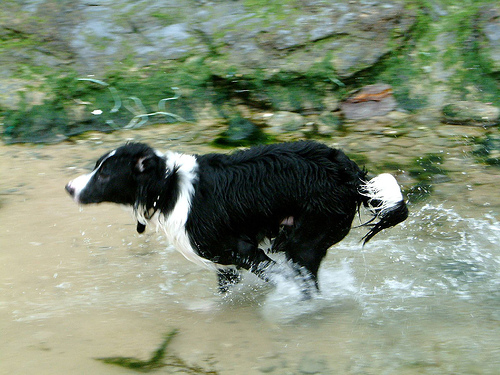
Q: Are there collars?
A: Yes, there is a collar.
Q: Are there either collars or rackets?
A: Yes, there is a collar.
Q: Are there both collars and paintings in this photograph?
A: No, there is a collar but no paintings.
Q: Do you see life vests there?
A: No, there are no life vests.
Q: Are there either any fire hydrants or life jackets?
A: No, there are no life jackets or fire hydrants.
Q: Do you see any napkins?
A: No, there are no napkins.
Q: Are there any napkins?
A: No, there are no napkins.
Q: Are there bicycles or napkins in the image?
A: No, there are no napkins or bicycles.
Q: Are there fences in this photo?
A: No, there are no fences.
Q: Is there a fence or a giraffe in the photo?
A: No, there are no fences or giraffes.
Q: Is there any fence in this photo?
A: No, there are no fences.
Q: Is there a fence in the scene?
A: No, there are no fences.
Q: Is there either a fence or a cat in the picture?
A: No, there are no fences or cats.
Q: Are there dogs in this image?
A: Yes, there is a dog.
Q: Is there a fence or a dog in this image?
A: Yes, there is a dog.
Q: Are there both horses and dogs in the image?
A: No, there is a dog but no horses.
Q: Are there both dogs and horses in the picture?
A: No, there is a dog but no horses.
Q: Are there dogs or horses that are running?
A: Yes, the dog is running.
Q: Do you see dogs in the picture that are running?
A: Yes, there is a dog that is running.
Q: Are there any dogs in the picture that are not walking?
A: Yes, there is a dog that is running.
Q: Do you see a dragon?
A: No, there are no dragons.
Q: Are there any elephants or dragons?
A: No, there are no dragons or elephants.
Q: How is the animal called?
A: The animal is a dog.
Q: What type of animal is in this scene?
A: The animal is a dog.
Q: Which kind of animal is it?
A: The animal is a dog.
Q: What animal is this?
A: That is a dog.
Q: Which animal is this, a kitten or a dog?
A: That is a dog.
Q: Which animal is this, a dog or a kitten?
A: That is a dog.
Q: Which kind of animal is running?
A: The animal is a dog.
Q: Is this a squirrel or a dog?
A: This is a dog.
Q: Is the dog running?
A: Yes, the dog is running.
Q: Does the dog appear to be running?
A: Yes, the dog is running.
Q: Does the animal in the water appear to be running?
A: Yes, the dog is running.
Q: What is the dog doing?
A: The dog is running.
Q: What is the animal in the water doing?
A: The dog is running.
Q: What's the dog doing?
A: The dog is running.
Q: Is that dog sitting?
A: No, the dog is running.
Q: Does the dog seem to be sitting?
A: No, the dog is running.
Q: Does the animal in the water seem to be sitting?
A: No, the dog is running.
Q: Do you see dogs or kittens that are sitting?
A: No, there is a dog but it is running.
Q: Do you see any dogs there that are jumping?
A: No, there is a dog but it is running.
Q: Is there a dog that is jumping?
A: No, there is a dog but it is running.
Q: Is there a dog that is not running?
A: No, there is a dog but it is running.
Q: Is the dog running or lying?
A: The dog is running.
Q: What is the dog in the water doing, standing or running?
A: The dog is running.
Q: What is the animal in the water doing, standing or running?
A: The dog is running.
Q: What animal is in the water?
A: The dog is in the water.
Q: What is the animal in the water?
A: The animal is a dog.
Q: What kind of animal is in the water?
A: The animal is a dog.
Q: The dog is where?
A: The dog is in the water.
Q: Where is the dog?
A: The dog is in the water.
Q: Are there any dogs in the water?
A: Yes, there is a dog in the water.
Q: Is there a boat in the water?
A: No, there is a dog in the water.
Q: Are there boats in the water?
A: No, there is a dog in the water.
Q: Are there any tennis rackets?
A: No, there are no tennis rackets.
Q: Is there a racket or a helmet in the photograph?
A: No, there are no rackets or helmets.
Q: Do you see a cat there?
A: No, there are no cats.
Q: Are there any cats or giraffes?
A: No, there are no cats or giraffes.